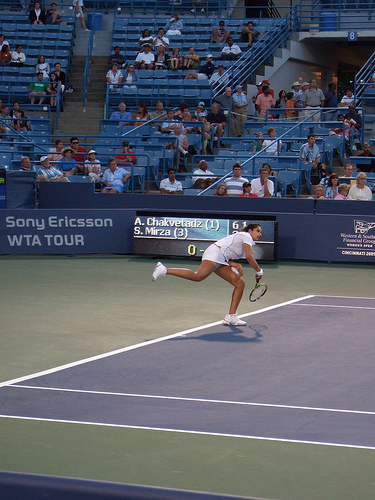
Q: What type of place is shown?
A: It is a stadium.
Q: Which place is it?
A: It is a stadium.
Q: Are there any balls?
A: No, there are no balls.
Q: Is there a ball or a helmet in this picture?
A: No, there are no balls or helmets.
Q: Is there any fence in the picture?
A: No, there are no fences.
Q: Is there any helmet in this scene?
A: No, there are no helmets.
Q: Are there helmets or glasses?
A: No, there are no helmets or glasses.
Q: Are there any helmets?
A: No, there are no helmets.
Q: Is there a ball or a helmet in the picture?
A: No, there are no helmets or balls.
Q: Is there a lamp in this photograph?
A: No, there are no lamps.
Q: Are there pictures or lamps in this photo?
A: No, there are no lamps or pictures.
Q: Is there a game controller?
A: Yes, there is a game controller.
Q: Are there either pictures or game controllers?
A: Yes, there is a game controller.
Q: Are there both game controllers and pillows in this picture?
A: No, there is a game controller but no pillows.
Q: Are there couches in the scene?
A: No, there are no couches.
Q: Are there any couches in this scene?
A: No, there are no couches.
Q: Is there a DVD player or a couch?
A: No, there are no couches or DVD players.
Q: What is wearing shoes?
A: The game controller is wearing shoes.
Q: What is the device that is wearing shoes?
A: The device is a game controller.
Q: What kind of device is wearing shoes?
A: The device is a game controller.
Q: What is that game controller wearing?
A: The game controller is wearing shoes.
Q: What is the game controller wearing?
A: The game controller is wearing shoes.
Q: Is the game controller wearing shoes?
A: Yes, the game controller is wearing shoes.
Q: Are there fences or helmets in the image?
A: No, there are no helmets or fences.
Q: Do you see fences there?
A: No, there are no fences.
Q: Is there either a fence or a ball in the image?
A: No, there are no fences or balls.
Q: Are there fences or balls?
A: No, there are no fences or balls.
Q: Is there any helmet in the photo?
A: No, there are no helmets.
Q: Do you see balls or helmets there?
A: No, there are no helmets or balls.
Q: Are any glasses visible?
A: No, there are no glasses.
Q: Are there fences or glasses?
A: No, there are no glasses or fences.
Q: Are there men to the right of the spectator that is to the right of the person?
A: Yes, there is a man to the right of the spectator.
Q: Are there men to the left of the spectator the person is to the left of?
A: No, the man is to the right of the spectator.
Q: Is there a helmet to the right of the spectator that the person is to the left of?
A: No, there is a man to the right of the spectator.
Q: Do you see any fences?
A: No, there are no fences.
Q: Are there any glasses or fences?
A: No, there are no fences or glasses.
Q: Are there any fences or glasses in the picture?
A: No, there are no fences or glasses.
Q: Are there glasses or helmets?
A: No, there are no glasses or helmets.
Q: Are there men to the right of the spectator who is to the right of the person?
A: Yes, there is a man to the right of the spectator.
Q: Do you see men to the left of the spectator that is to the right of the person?
A: No, the man is to the right of the spectator.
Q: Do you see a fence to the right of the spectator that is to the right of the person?
A: No, there is a man to the right of the spectator.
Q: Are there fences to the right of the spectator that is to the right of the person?
A: No, there is a man to the right of the spectator.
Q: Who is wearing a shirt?
A: The man is wearing a shirt.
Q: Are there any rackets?
A: Yes, there is a racket.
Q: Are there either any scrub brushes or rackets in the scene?
A: Yes, there is a racket.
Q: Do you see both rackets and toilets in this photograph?
A: No, there is a racket but no toilets.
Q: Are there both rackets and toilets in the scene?
A: No, there is a racket but no toilets.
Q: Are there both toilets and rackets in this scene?
A: No, there is a racket but no toilets.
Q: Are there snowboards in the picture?
A: No, there are no snowboards.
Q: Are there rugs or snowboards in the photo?
A: No, there are no snowboards or rugs.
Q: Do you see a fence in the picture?
A: No, there are no fences.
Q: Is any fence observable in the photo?
A: No, there are no fences.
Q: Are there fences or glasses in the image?
A: No, there are no fences or glasses.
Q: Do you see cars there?
A: No, there are no cars.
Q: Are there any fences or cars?
A: No, there are no cars or fences.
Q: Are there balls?
A: No, there are no balls.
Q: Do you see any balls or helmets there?
A: No, there are no balls or helmets.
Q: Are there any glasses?
A: No, there are no glasses.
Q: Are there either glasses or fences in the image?
A: No, there are no glasses or fences.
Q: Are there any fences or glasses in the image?
A: No, there are no glasses or fences.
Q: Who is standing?
A: The man is standing.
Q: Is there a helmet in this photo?
A: No, there are no helmets.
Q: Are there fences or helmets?
A: No, there are no helmets or fences.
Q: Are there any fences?
A: No, there are no fences.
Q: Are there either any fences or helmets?
A: No, there are no fences or helmets.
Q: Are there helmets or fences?
A: No, there are no fences or helmets.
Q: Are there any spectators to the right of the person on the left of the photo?
A: Yes, there is a spectator to the right of the person.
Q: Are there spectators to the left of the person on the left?
A: No, the spectator is to the right of the person.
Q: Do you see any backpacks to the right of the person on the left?
A: No, there is a spectator to the right of the person.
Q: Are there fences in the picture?
A: No, there are no fences.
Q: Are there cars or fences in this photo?
A: No, there are no fences or cars.